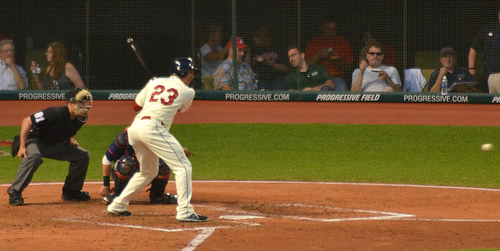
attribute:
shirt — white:
[133, 73, 197, 120]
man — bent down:
[5, 82, 92, 204]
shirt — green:
[281, 66, 326, 96]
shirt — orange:
[303, 38, 358, 75]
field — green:
[0, 0, 497, 243]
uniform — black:
[5, 68, 110, 210]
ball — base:
[478, 139, 493, 157]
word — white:
[312, 87, 363, 102]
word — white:
[360, 92, 380, 103]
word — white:
[402, 92, 474, 103]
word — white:
[225, 92, 291, 100]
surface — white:
[219, 215, 274, 217]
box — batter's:
[83, 187, 293, 248]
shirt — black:
[20, 87, 104, 156]